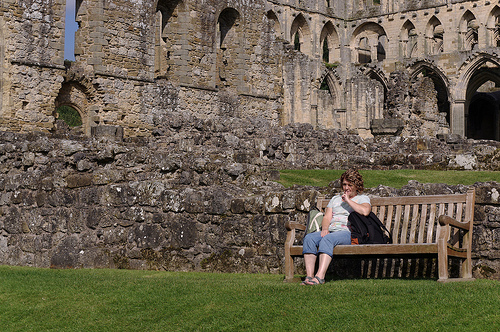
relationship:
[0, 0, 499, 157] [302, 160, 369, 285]
building behind lady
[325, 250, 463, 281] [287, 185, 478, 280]
shadows underneath bench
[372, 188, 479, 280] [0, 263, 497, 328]
wooden bench on grass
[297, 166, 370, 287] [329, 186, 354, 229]
lady wearing shirt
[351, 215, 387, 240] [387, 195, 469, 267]
bag on bench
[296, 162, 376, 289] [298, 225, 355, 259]
lady wears capris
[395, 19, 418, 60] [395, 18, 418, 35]
window has arch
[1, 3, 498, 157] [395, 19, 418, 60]
building has window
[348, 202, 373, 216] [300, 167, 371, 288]
arm of person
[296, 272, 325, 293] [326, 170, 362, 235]
feet of person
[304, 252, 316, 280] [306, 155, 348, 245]
leg of person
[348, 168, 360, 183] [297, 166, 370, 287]
hair of lady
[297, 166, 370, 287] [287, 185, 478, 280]
lady on bench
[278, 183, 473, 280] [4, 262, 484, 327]
wooden bench on lawn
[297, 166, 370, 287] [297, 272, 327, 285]
lady wearing sandals